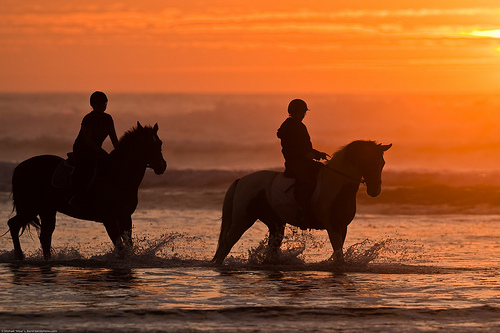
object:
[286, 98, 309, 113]
head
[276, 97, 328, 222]
people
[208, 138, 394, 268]
animals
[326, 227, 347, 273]
legs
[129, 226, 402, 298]
water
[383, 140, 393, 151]
ear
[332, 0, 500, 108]
sunset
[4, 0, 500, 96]
sky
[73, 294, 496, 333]
land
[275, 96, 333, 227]
person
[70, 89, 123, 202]
person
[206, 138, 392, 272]
horse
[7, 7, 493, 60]
clouds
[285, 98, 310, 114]
helmet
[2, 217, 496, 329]
water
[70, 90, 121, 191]
people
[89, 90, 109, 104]
helmet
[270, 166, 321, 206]
saddle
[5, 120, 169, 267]
horse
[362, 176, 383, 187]
bridle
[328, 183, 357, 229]
spot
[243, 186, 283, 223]
spot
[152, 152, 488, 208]
waves